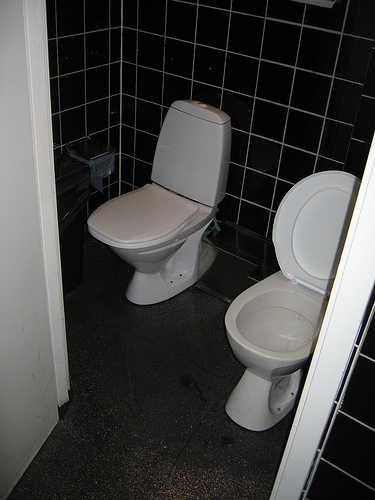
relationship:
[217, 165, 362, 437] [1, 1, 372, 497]
toilet in bathroom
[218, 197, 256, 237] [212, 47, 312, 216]
tile on wall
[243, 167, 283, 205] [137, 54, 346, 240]
tile on wall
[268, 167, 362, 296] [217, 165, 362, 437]
seat on toilet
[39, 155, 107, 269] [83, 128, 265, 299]
can in bathroom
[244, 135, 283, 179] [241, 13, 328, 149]
tile on wall